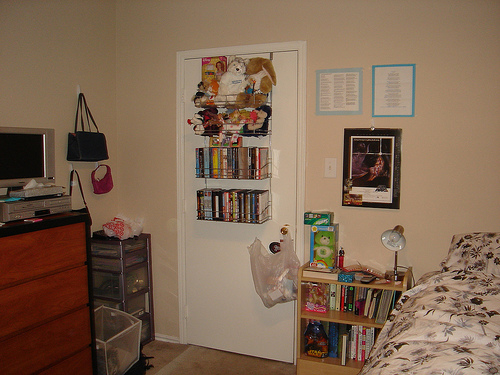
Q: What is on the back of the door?
A: Books and stuffed animals.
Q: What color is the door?
A: White.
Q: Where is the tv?
A: On the dresser.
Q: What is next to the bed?
A: A bookshelf.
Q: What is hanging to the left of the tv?
A: A purse.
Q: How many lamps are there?
A: 1.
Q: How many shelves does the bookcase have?
A: 2.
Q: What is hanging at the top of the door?
A: Plush animals.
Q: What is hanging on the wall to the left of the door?
A: Purses.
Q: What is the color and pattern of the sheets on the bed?
A: Black and white floral.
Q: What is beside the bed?
A: Wooden book shelf.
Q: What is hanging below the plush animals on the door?
A: Books.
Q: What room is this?
A: Bedroom.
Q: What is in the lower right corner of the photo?
A: Bed.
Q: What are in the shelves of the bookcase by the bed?
A: Books.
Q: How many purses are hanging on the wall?
A: Three.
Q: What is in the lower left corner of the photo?
A: Dresser.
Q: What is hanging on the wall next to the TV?
A: Purses.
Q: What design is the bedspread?
A: Floral.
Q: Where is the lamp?
A: Next to the bed.